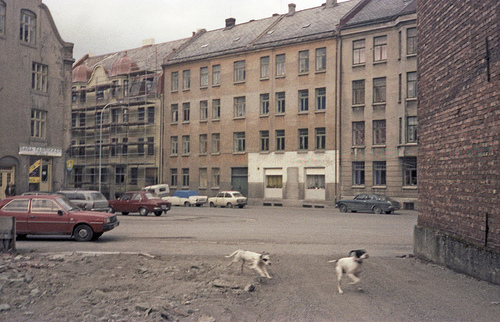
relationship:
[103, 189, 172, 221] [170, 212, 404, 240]
red car parked in street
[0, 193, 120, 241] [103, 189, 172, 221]
car parked in red car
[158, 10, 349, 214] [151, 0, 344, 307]
building in center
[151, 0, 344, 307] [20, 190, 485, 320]
center of street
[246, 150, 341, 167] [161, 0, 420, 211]
white section part of building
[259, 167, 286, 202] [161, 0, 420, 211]
garage door part of building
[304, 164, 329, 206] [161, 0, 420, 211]
garage door part of building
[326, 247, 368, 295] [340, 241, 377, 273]
dogs with face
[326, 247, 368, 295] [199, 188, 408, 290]
dogs in street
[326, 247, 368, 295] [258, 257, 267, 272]
dogs with eye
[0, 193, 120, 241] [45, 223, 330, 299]
car in street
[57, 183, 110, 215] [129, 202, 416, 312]
car in street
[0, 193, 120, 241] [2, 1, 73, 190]
car parked in front of stone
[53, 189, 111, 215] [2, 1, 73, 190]
car parked in front of stone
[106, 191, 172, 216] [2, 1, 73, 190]
red car parked in front of stone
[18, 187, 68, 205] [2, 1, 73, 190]
car parked in front of stone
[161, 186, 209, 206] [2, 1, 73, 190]
car parked in front of stone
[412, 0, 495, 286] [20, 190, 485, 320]
brick wall lining street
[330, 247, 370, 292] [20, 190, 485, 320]
dogs running on street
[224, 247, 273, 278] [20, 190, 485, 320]
dogs running on street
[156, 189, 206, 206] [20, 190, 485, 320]
car parked on street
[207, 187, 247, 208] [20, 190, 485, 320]
car parked on street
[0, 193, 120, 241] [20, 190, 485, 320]
car parked on street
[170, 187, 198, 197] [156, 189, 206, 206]
top covering car